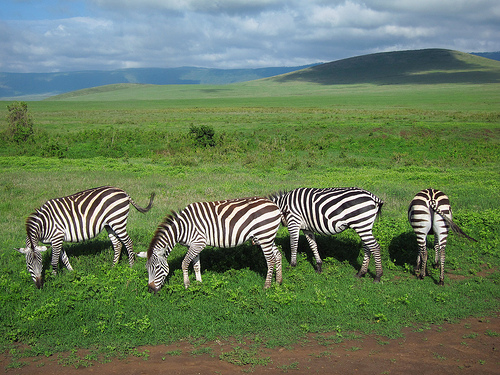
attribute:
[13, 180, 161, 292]
zebra — standing, eating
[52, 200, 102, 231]
stripes — black, white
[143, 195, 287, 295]
zebra — standing, eating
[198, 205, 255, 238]
stripes — black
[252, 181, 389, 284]
zebra — standing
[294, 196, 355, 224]
stripes — white, black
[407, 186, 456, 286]
zebra — standing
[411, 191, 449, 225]
stripes — white, black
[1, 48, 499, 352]
grass — green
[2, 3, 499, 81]
sky — blue